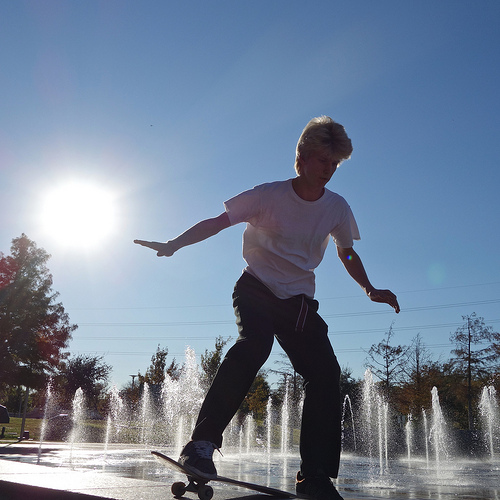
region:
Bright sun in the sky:
[25, 170, 130, 257]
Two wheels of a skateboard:
[168, 476, 217, 497]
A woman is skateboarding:
[130, 110, 405, 495]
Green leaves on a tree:
[0, 226, 80, 387]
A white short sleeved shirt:
[220, 171, 361, 301]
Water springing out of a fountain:
[0, 342, 495, 497]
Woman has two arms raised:
[131, 110, 401, 315]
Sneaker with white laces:
[175, 432, 222, 477]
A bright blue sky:
[0, 1, 496, 389]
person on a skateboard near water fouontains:
[132, 107, 403, 499]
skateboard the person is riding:
[147, 443, 307, 496]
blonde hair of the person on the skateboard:
[292, 116, 351, 172]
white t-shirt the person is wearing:
[220, 182, 358, 298]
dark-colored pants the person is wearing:
[194, 272, 344, 479]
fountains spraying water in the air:
[39, 350, 496, 499]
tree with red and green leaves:
[1, 235, 73, 437]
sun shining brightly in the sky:
[38, 175, 119, 251]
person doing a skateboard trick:
[136, 120, 407, 497]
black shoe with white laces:
[177, 434, 219, 480]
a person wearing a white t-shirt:
[131, 113, 401, 499]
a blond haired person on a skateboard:
[133, 113, 400, 499]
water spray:
[16, 340, 496, 493]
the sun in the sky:
[28, 169, 120, 265]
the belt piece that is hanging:
[293, 299, 308, 334]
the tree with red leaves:
[1, 234, 62, 439]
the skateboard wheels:
[173, 480, 211, 499]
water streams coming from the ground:
[413, 395, 453, 485]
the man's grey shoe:
[179, 438, 219, 479]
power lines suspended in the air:
[424, 296, 448, 346]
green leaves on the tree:
[3, 256, 62, 366]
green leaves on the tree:
[48, 347, 88, 403]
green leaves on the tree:
[81, 370, 117, 435]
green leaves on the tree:
[146, 360, 172, 398]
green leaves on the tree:
[195, 336, 226, 397]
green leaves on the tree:
[223, 373, 279, 435]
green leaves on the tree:
[253, 350, 309, 422]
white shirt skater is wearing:
[225, 172, 359, 302]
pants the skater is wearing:
[188, 265, 350, 473]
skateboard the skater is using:
[140, 448, 305, 498]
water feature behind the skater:
[6, 335, 498, 491]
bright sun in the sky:
[35, 163, 114, 254]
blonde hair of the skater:
[293, 111, 358, 149]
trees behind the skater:
[3, 239, 499, 428]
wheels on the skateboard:
[167, 470, 214, 499]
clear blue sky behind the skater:
[2, 7, 499, 365]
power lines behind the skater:
[58, 296, 498, 380]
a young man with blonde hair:
[289, 110, 356, 182]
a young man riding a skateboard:
[152, 440, 345, 497]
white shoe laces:
[192, 435, 224, 459]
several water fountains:
[356, 371, 493, 483]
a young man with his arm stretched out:
[128, 180, 273, 272]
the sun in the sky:
[14, 148, 132, 258]